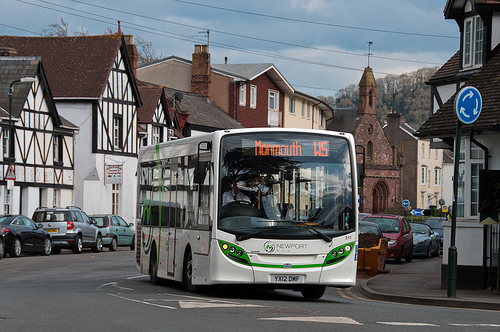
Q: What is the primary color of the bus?
A: White.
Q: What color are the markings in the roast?
A: White.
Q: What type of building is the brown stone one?
A: Church.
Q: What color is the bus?
A: White and green.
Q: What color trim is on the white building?
A: Brown.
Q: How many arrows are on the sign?
A: Three.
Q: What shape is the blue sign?
A: Round.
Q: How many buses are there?
A: One.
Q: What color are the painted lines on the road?
A: White.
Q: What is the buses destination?
A: Monmouth.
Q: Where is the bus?
A: In the street.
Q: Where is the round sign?
A: On the pole.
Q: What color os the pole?
A: Green.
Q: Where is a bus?
A: On the road.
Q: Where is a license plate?
A: On front of the bus.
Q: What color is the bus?
A: White and Green.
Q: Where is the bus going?
A: Monmouth WS.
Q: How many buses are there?
A: One.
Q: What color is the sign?
A: Blue.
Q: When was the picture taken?
A: Daytime.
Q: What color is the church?
A: Brown.